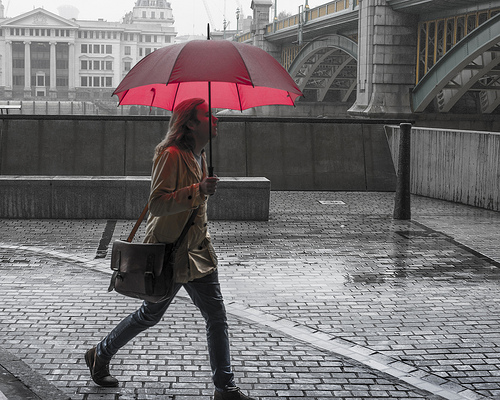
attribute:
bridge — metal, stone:
[205, 1, 483, 117]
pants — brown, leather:
[94, 265, 236, 389]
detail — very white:
[7, 26, 27, 36]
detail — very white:
[27, 27, 53, 36]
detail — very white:
[51, 28, 71, 38]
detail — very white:
[7, 11, 73, 25]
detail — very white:
[78, 29, 118, 40]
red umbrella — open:
[132, 39, 281, 107]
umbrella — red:
[102, 5, 300, 129]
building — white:
[9, 8, 152, 100]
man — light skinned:
[101, 64, 289, 399]